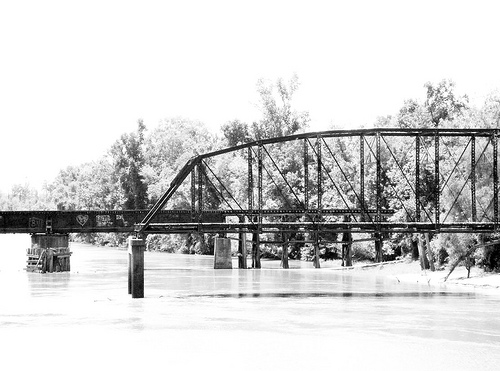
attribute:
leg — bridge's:
[120, 215, 162, 297]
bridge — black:
[5, 109, 499, 271]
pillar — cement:
[28, 232, 69, 272]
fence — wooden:
[236, 221, 431, 276]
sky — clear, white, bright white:
[0, 0, 499, 209]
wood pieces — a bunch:
[27, 243, 72, 273]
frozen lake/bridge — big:
[130, 160, 392, 363]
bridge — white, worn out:
[8, 117, 498, 294]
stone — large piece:
[207, 232, 243, 280]